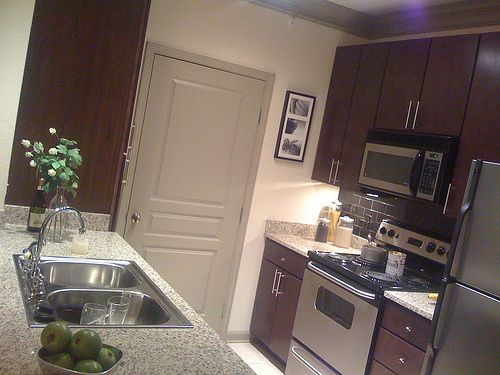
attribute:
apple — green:
[40, 320, 72, 354]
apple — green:
[70, 329, 105, 356]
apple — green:
[96, 347, 119, 369]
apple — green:
[45, 353, 74, 368]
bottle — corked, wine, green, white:
[27, 175, 49, 229]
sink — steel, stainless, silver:
[44, 286, 170, 327]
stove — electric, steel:
[286, 224, 454, 374]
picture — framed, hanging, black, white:
[274, 88, 316, 164]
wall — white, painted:
[149, 0, 374, 344]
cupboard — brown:
[375, 35, 478, 134]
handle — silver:
[404, 101, 412, 130]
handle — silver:
[412, 99, 419, 130]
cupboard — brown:
[312, 43, 390, 190]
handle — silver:
[327, 159, 334, 183]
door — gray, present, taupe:
[118, 39, 277, 340]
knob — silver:
[129, 212, 144, 225]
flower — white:
[47, 126, 57, 134]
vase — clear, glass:
[45, 184, 70, 243]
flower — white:
[18, 136, 32, 149]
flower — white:
[28, 159, 37, 167]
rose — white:
[47, 169, 58, 177]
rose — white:
[21, 139, 32, 147]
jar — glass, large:
[326, 197, 345, 244]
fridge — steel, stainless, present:
[422, 157, 500, 374]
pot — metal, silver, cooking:
[362, 232, 387, 265]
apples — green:
[37, 322, 116, 371]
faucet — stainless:
[36, 205, 88, 259]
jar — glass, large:
[333, 214, 355, 249]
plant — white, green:
[20, 127, 85, 198]